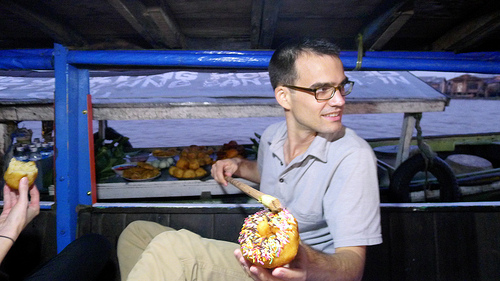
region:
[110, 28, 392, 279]
person sitting down holding a donut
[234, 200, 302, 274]
the donut is large and has sprinkles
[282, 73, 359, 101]
a pair of black eye glasses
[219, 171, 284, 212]
long wooden stick of unknown use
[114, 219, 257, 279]
a pair of khaki colored pants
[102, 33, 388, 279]
person is wearing khaki pants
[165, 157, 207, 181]
tray full of food on table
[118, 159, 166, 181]
tray full of food on table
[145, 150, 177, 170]
tray full of food on table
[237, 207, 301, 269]
Sprinkled multi color donut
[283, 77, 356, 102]
Men's eye glasses on face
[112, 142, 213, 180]
Serving of goodies on a table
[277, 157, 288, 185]
Male shirt buttons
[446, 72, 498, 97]
Houses on the side of the water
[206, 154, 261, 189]
A man's right hand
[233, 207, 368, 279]
Left man's hand holding a donut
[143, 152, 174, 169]
White eggs served on a table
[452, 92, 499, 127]
The calm sea water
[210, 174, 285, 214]
Wooden long circular stick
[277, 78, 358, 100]
a man's eyeglasses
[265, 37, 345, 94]
a man's short cut black hair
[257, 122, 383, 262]
a man's short sleeve shirt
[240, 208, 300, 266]
a doughnut with sprinkles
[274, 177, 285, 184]
a small button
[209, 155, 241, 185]
the hand of a man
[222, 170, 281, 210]
a long wooden pole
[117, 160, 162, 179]
a plate of food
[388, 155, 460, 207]
part of a black tire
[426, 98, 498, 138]
a section of water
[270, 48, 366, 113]
the man is wearing glasses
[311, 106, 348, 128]
the teeth are showing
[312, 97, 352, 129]
the man is smiling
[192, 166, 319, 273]
the man is holding a donut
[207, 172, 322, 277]
the donut has sprinkles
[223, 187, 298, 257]
the sprinkles are multi colored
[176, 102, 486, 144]
water is in the background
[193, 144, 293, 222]
the man is holding a stick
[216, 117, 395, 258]
the shirt is short sleeved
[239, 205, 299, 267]
the donut in the man's hand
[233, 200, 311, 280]
the left hand holding the donut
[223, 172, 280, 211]
the wooden stick in the man's hand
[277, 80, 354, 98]
the glasses on the man's face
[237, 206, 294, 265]
the sprinkles on the donut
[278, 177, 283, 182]
the button on the man's shirt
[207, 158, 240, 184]
the right hand holding the stick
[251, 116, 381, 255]
the short sleeved shirt on the man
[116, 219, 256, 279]
the long pants on the man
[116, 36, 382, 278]
the man sitting and holding a donut